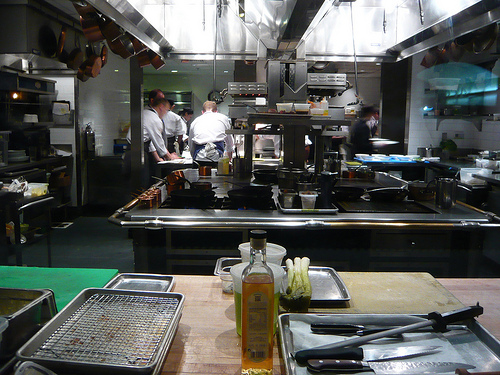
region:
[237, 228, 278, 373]
Bottle of oil on a table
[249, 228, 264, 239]
Black cap on a bottle of oil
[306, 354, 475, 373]
Knife lying on a tray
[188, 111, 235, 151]
White shirt on a man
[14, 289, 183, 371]
Metal tray on a table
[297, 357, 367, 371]
Brown handle on a knife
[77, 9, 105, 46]
hanging copper colored pot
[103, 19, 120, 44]
hanging copper colored pot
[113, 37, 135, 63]
hanging copper colored pot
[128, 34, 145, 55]
hanging copper colored pot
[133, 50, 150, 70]
hanging copper colored pot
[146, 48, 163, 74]
hanging copper colored pot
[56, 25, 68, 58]
hanging copper colored pot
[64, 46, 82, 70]
hanging copper colored pot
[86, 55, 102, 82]
hanging copper colored pot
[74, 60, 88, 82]
hanging copper colored pot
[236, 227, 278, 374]
bottle of oil on a counter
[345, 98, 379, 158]
person wearing a dark shirt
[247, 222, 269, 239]
black cap on a bottle of oil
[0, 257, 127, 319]
green surface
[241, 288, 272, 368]
label on a bottle of oil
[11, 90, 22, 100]
orange light on a stove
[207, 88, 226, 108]
clock on the wall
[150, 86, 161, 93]
a man's balding hair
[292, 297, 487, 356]
meat thermometer on a tray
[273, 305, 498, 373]
silver tray of utinsils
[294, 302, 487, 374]
A tray of utensils.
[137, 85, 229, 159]
A group of cook's standing grouped together.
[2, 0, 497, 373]
A large commercial kitchen.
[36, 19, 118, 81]
Pans hanging from the ceiling.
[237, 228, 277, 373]
A bottle containing oil.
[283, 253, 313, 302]
A bunch of veggies together.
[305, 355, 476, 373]
A sharp knife.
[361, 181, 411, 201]
A frying pan.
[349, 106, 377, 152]
A person in black moving right.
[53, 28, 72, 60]
copper colored cooking pot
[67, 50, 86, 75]
copper colored cooking pot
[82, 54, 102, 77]
copper colored cooking pot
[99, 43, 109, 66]
copper colored cooking pot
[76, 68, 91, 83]
copper colored cooking pot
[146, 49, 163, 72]
copper colored cooking pot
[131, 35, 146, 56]
copper colored cooking pot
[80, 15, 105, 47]
copper colored cooking pot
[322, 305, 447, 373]
Knives on the silver pan.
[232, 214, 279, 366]
A bottle sitting on the counter.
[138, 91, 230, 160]
People in the kitchen cooking.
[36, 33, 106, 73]
Pots hanging from the ceiling.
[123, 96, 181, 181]
person wearing white shirt in kitchen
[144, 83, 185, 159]
person wearing white shirt in kitchen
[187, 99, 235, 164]
person wearing white shirt in kitchen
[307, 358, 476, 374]
knife laying on tray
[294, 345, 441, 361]
knife laying on tray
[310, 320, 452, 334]
knife laying on tray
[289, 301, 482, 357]
knife sharpener laying on tray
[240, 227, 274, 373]
glass bottle on wooden surface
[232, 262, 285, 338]
plastic container on wooden surface